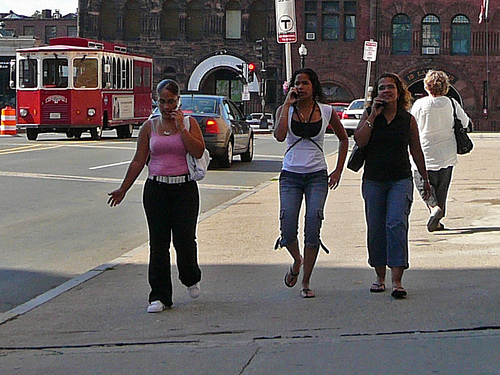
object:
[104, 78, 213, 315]
woman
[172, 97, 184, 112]
cell phone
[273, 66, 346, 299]
woman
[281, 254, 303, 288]
sandals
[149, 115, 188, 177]
pink shirt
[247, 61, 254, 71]
streetlight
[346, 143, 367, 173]
purse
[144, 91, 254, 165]
car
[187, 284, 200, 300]
white shoes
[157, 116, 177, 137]
necklace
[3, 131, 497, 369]
sidewalk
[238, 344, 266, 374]
crack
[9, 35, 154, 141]
trolley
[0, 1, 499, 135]
building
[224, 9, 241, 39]
window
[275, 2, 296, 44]
sign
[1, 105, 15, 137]
barrel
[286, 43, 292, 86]
pole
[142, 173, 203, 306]
pants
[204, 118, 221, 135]
light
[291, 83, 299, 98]
cell phone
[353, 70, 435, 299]
woman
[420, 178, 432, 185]
bracelet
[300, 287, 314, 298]
sandal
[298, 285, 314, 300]
foot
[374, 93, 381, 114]
cell phone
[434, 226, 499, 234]
shadow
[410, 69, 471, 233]
woman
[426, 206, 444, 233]
shoe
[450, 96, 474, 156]
purse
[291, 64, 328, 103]
hair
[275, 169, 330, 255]
jeans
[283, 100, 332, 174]
shirt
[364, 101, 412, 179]
black shirt